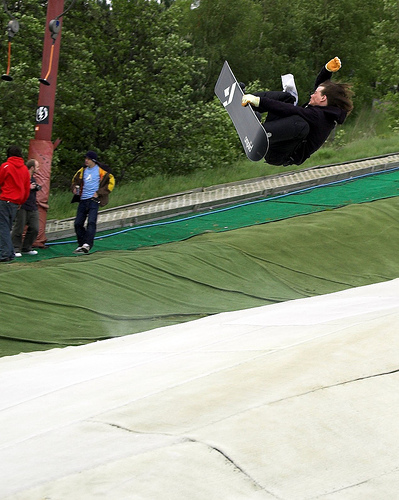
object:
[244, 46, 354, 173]
man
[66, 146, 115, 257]
man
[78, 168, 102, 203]
shirt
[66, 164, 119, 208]
jacket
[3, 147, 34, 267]
man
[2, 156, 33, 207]
jacket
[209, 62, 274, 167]
snowboard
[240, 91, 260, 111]
glove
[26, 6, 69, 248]
pole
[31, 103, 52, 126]
sticker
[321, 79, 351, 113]
hair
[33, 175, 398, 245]
hose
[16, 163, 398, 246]
mats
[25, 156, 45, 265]
man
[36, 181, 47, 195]
camera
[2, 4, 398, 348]
air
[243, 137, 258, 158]
letters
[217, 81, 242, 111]
design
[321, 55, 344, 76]
glove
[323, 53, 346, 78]
hand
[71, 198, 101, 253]
jeans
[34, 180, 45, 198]
soda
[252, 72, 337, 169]
black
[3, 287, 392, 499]
ground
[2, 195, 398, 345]
mats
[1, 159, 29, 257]
back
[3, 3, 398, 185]
trees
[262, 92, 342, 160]
shirt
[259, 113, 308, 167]
pants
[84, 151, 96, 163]
hat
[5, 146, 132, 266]
people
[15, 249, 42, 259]
shoes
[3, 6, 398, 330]
background